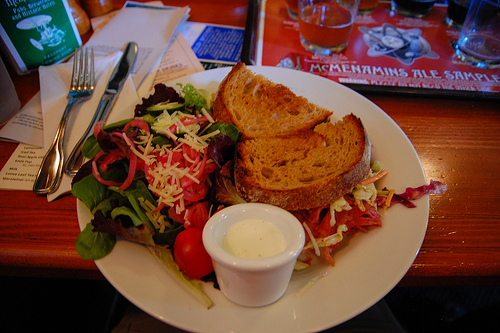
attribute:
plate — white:
[68, 60, 442, 330]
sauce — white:
[215, 214, 282, 268]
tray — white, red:
[241, 5, 499, 95]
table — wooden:
[2, 2, 498, 276]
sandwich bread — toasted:
[212, 67, 373, 212]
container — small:
[197, 196, 317, 317]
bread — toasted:
[212, 58, 372, 216]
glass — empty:
[452, 9, 499, 72]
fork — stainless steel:
[28, 40, 106, 192]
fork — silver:
[50, 43, 113, 184]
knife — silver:
[99, 41, 151, 101]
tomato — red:
[156, 224, 204, 273]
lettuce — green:
[64, 207, 114, 270]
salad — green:
[69, 131, 150, 259]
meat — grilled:
[295, 189, 374, 251]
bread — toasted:
[193, 49, 307, 144]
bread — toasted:
[234, 136, 370, 226]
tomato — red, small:
[156, 218, 226, 295]